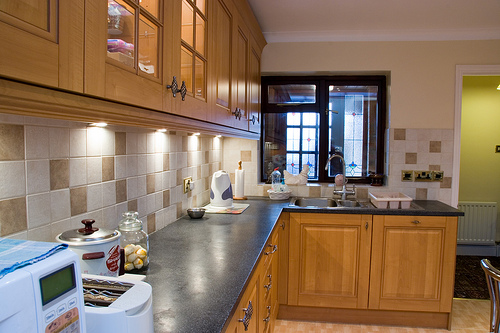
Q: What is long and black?
A: The countertop.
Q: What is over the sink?
A: Windows.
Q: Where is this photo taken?
A: A kitchen.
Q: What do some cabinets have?
A: Windows.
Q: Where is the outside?
A: Beyond the window.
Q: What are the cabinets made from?
A: Wood.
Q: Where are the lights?
A: Under the cabinet.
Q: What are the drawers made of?
A: Wood.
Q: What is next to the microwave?
A: A toaster.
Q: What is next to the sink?
A: A dish rack.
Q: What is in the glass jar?
A: Cookies.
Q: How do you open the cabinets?
A: With the knobs.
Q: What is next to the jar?
A: A slow cooker.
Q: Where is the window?
A: Above the sink.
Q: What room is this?
A: Kitchen.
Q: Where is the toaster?
A: Next to the microwave.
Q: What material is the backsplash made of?
A: Tile.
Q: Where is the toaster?
A: Counter.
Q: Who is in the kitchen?
A: No one.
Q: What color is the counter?
A: Black.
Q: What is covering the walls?
A: Tiles.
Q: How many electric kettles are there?
A: One.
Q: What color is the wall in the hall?
A: Green.